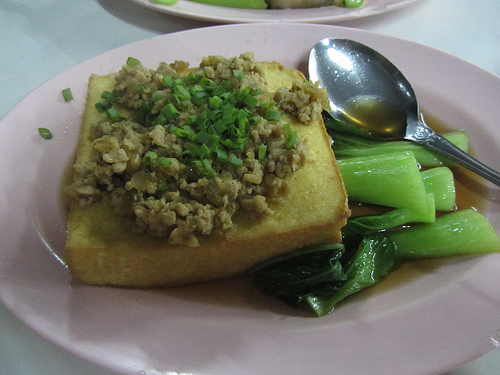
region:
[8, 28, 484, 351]
A meal on a plate.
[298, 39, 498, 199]
A silver colored spoon.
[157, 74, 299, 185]
Green vegetable on the food.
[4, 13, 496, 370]
A ceramic plate of food.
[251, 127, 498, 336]
A green vegetable in broth.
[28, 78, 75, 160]
Chives on the side of a plate.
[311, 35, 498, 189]
spoon on the plate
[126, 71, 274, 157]
green garnish on the bread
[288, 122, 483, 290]
green vegetables on the plate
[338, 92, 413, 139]
liquid on the spoon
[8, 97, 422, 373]
shadow of the food on the plate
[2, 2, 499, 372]
two white plates on the table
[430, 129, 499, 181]
handle of the silver spoon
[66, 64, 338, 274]
buttered piece of bread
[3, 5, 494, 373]
tablecloth underneath the plates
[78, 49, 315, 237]
brown garnish on the bread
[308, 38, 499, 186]
metal spoon on bowl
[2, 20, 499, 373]
white plate is circular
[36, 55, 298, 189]
green onions sliced on top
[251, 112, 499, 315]
leafy green vegetable on plate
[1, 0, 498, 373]
blue table top under plates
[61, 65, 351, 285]
bread slice under green onions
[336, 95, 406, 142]
small amount of broth in spoon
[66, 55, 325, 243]
ground brown meat on bread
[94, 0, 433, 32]
shadow on table under top plate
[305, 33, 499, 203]
A table spoon with liquid in it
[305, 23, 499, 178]
A table spoon resting on a plate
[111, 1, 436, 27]
Another filled plate in the background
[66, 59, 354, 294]
A thick sliced piece of bread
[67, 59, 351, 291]
An openfaced sandwich of sorts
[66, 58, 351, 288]
Chives cover the top of the breaded meal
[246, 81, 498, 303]
Green leafy vegetables in juices as a side dish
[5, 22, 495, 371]
A white plate holds a bread and vegetable meal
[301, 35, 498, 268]
A silver spoon rests on top of green leafy vegetables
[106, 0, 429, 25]
white plate behind a plate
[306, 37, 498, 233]
silver spoon on top of a plate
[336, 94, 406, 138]
liquid inside the spoon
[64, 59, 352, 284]
slice of bread on top of a plate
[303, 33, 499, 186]
gray metal spoon on white plate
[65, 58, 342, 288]
slice of bread on white plate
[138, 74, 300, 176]
chopped chives on top of tuna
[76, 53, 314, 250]
tuna on top of bread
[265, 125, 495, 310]
green vegetables on a plate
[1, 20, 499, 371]
white plate at the bottom of picture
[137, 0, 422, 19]
frame of white plate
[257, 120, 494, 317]
green chard on white plate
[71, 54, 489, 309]
vegetarian food on white plate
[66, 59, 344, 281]
butter sliced bread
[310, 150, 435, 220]
A piece of food on a dish.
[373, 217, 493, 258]
A piece of food on a dish.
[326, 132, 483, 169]
A piece of food on a dish.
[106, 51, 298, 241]
A piece of food on a dish.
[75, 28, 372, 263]
A piece of food on a dish.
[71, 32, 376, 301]
A piece of food on a dish.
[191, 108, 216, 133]
A piece of food on a dish.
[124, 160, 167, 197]
A piece of food on a dish.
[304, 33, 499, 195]
silver spoon on plate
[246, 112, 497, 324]
broccoli on plate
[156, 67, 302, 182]
green seasoning on top of cooked food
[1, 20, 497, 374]
white plate underneath food